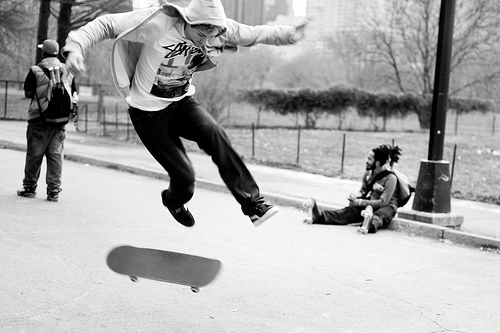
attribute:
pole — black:
[415, 0, 454, 200]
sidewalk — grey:
[270, 159, 337, 196]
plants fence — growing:
[233, 81, 454, 131]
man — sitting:
[311, 139, 421, 236]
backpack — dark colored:
[33, 58, 75, 127]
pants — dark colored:
[123, 96, 265, 213]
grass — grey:
[268, 130, 497, 185]